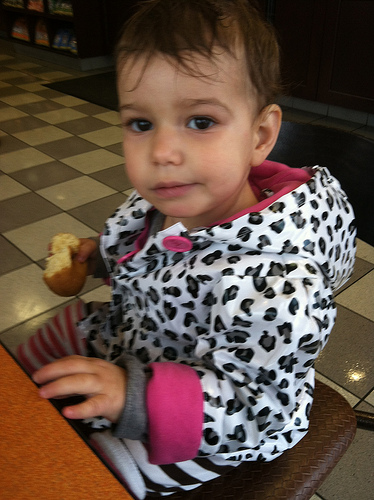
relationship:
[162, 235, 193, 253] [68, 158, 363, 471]
button on jacket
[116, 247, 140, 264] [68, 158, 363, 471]
button on jacket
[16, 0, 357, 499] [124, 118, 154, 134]
baby has eye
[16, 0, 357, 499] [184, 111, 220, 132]
baby has eye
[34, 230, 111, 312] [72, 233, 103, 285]
snack in hand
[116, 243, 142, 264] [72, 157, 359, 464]
button on coat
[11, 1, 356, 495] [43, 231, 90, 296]
baby holding donut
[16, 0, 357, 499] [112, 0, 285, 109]
baby has brown hair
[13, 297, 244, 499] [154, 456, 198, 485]
pants has stripe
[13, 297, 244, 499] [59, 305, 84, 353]
pants has stripe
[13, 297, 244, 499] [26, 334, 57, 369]
pants has stripe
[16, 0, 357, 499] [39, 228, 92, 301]
baby eats doughnut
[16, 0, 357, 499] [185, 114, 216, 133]
baby has eye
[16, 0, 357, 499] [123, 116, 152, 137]
baby has brown eyes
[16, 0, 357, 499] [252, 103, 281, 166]
baby has ear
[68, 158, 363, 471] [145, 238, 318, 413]
jacket has leapord spots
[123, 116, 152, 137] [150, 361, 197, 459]
brown eyes has pink cuffs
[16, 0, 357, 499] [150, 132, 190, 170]
baby has nose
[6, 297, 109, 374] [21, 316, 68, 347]
pants has stripes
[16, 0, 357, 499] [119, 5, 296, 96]
baby has brown hair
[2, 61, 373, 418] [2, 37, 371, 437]
tiles on floor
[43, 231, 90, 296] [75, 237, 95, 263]
donut in a hand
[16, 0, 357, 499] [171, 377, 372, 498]
baby sitting on chair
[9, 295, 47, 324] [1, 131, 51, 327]
light bouncing off tiles